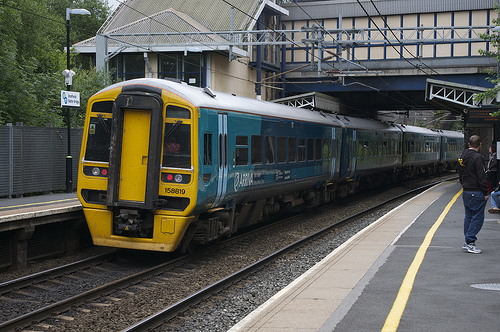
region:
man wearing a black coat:
[458, 134, 492, 254]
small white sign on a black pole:
[60, 89, 80, 106]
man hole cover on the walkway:
[471, 279, 499, 290]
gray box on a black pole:
[61, 69, 76, 86]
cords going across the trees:
[6, 2, 283, 91]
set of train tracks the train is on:
[1, 246, 178, 328]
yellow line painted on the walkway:
[376, 189, 463, 331]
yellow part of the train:
[77, 82, 197, 254]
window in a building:
[156, 54, 206, 89]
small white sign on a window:
[188, 77, 196, 82]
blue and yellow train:
[73, 81, 478, 276]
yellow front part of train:
[79, 84, 195, 251]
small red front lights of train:
[97, 167, 176, 181]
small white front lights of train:
[88, 165, 186, 186]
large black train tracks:
[1, 155, 472, 327]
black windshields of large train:
[86, 117, 189, 170]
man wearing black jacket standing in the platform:
[453, 135, 490, 255]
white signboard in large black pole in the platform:
[61, 88, 83, 111]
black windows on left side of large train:
[202, 130, 467, 172]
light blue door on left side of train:
[213, 109, 233, 203]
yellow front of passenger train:
[77, 80, 202, 254]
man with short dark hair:
[458, 132, 484, 157]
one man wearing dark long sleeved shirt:
[456, 133, 492, 193]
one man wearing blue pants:
[455, 134, 490, 259]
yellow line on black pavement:
[380, 181, 465, 331]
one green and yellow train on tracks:
[22, 71, 463, 301]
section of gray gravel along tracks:
[181, 264, 268, 321]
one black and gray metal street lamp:
[59, 5, 91, 82]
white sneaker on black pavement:
[458, 239, 485, 261]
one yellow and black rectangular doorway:
[106, 95, 164, 209]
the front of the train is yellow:
[37, 45, 219, 250]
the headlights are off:
[40, 146, 192, 192]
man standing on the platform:
[452, 115, 492, 265]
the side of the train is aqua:
[169, 86, 364, 196]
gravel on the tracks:
[131, 255, 268, 305]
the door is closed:
[100, 90, 161, 210]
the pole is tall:
[53, 1, 81, 188]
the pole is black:
[49, 27, 76, 192]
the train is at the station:
[47, 72, 454, 238]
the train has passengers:
[73, 82, 444, 188]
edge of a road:
[366, 208, 377, 221]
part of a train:
[219, 175, 228, 187]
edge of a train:
[214, 175, 224, 197]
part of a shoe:
[456, 230, 463, 236]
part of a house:
[235, 91, 249, 115]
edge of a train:
[176, 153, 184, 163]